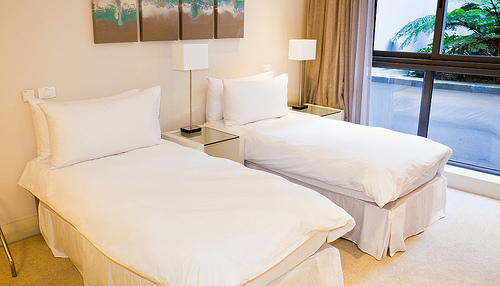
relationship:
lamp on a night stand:
[169, 40, 210, 140] [165, 125, 243, 164]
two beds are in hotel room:
[16, 70, 452, 285] [1, 0, 500, 285]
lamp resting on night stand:
[169, 40, 210, 140] [165, 125, 243, 164]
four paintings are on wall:
[89, 1, 248, 47] [2, 0, 307, 246]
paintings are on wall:
[89, 1, 248, 47] [2, 0, 307, 246]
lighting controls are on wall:
[18, 85, 59, 106] [2, 0, 307, 246]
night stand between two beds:
[165, 125, 243, 164] [16, 70, 452, 285]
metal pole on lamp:
[185, 68, 195, 128] [169, 40, 210, 140]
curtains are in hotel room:
[305, 1, 375, 127] [1, 0, 500, 285]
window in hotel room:
[370, 1, 500, 178] [1, 0, 500, 285]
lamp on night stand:
[169, 40, 210, 140] [165, 125, 243, 164]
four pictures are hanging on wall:
[89, 1, 248, 47] [2, 0, 307, 246]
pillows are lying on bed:
[25, 83, 165, 172] [17, 83, 360, 282]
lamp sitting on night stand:
[169, 40, 210, 140] [165, 125, 243, 164]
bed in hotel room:
[17, 83, 360, 282] [1, 0, 500, 285]